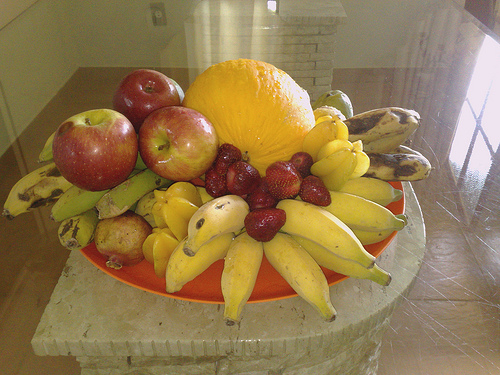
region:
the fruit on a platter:
[4, 58, 433, 325]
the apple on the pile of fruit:
[51, 106, 136, 189]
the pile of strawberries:
[205, 144, 331, 242]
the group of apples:
[49, 69, 218, 191]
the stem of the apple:
[155, 141, 170, 151]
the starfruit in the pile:
[151, 179, 203, 241]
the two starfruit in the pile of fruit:
[140, 179, 202, 277]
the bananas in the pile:
[1, 57, 435, 327]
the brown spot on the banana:
[195, 215, 204, 229]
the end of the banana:
[225, 317, 236, 327]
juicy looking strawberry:
[244, 206, 289, 243]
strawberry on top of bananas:
[241, 208, 287, 243]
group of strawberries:
[202, 143, 332, 242]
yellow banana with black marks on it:
[180, 188, 248, 258]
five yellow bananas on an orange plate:
[266, 188, 403, 321]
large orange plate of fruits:
[1, 54, 435, 327]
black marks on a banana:
[38, 166, 64, 182]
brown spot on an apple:
[56, 120, 75, 137]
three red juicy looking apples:
[54, 68, 219, 190]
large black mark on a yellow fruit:
[345, 109, 390, 136]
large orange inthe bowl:
[198, 70, 286, 165]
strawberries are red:
[211, 152, 316, 212]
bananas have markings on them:
[13, 176, 85, 262]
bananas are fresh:
[283, 192, 402, 312]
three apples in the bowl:
[65, 78, 217, 180]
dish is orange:
[114, 272, 287, 300]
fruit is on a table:
[79, 312, 374, 366]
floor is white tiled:
[421, 207, 496, 374]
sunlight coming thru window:
[448, 54, 497, 192]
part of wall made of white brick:
[281, 8, 329, 90]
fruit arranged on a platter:
[23, 63, 400, 310]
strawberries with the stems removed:
[214, 147, 320, 238]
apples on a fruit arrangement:
[50, 69, 206, 179]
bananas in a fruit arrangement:
[293, 203, 380, 281]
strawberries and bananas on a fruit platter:
[212, 172, 309, 264]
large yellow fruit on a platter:
[218, 63, 289, 153]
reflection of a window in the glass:
[439, 36, 494, 236]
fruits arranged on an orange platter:
[4, 65, 420, 314]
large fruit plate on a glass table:
[4, 70, 439, 320]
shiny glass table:
[435, 53, 483, 281]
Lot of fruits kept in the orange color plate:
[17, 44, 430, 306]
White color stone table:
[66, 293, 139, 350]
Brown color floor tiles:
[441, 261, 495, 352]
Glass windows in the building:
[464, 48, 490, 194]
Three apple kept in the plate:
[54, 67, 184, 156]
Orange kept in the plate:
[231, 59, 283, 114]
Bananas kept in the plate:
[180, 250, 373, 292]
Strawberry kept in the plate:
[233, 156, 288, 189]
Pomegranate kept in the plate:
[96, 229, 133, 278]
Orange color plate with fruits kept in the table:
[13, 35, 445, 368]